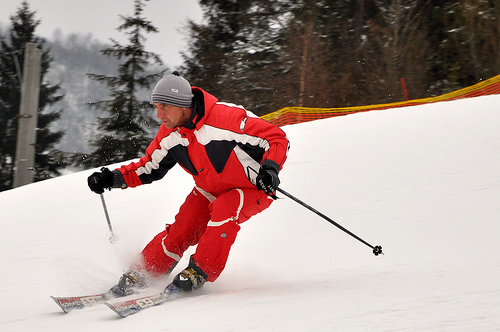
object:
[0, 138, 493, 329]
ground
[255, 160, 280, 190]
hand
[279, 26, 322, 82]
branch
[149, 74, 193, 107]
hat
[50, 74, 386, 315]
man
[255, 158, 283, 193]
glove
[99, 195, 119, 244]
ski pole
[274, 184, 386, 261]
ski pole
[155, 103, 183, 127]
face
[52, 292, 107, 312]
ski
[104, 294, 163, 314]
ski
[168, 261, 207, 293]
boot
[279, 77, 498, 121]
fence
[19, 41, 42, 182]
wood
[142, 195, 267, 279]
pants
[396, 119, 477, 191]
snow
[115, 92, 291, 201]
jacket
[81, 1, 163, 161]
trees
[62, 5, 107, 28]
sky